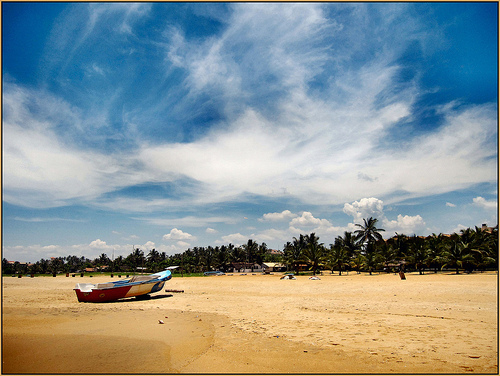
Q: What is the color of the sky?
A: Blue and white.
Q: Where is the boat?
A: On the shore.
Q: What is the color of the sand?
A: Brown.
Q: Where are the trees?
A: On the other side of shore.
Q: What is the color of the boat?
A: Red and blue.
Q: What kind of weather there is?
A: Sunny.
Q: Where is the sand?
A: On the beach.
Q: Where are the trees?
A: Bordering the shore.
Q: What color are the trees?
A: Green.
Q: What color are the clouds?
A: White.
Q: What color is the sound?
A: Brown.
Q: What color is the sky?
A: Blue.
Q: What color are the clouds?
A: White.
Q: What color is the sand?
A: Brown.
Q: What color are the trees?
A: Green.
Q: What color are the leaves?
A: Green.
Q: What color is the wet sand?
A: Brown.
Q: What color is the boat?
A: Red.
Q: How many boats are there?
A: One.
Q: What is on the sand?
A: A boat.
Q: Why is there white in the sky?
A: Clouds.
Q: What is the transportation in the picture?
A: Boat.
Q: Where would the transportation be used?
A: In the water.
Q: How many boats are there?
A: 1.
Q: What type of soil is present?
A: Sand.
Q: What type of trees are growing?
A: Palm trees.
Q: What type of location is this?
A: Beach.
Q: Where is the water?
A: To the left.